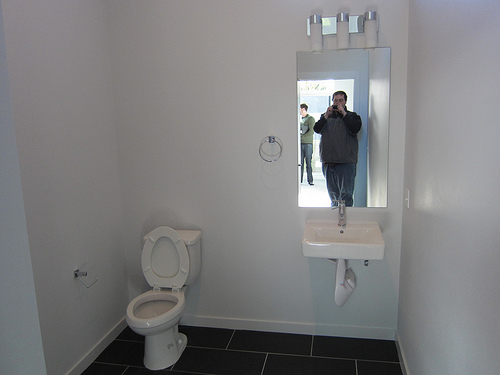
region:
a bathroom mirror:
[283, 46, 408, 195]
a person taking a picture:
[291, 43, 404, 203]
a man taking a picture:
[246, 73, 396, 190]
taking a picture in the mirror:
[303, 59, 410, 196]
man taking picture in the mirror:
[304, 74, 386, 204]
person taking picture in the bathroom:
[286, 80, 416, 205]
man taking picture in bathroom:
[293, 65, 385, 220]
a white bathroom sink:
[265, 182, 408, 316]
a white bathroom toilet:
[82, 196, 203, 373]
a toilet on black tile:
[132, 222, 332, 374]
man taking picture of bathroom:
[57, 35, 449, 331]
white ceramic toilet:
[115, 211, 215, 352]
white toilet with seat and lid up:
[122, 225, 197, 301]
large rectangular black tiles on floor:
[190, 330, 342, 365]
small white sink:
[290, 216, 386, 266]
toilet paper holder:
[66, 256, 102, 291]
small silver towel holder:
[250, 126, 281, 167]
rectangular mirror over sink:
[295, 42, 385, 238]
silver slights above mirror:
[297, 5, 373, 51]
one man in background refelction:
[301, 87, 323, 199]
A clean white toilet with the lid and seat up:
[126, 222, 191, 370]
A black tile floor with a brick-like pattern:
[78, 314, 404, 374]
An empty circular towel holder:
[255, 136, 285, 163]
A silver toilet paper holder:
[71, 260, 97, 290]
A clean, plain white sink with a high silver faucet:
[302, 205, 384, 309]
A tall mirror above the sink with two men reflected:
[295, 47, 389, 208]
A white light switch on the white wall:
[401, 188, 413, 209]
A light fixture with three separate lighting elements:
[303, 9, 382, 50]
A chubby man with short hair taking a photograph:
[313, 90, 361, 212]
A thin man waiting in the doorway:
[296, 102, 317, 185]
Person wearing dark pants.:
[313, 173, 365, 220]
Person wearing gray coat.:
[314, 135, 340, 158]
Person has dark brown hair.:
[327, 84, 354, 101]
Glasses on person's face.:
[328, 96, 403, 119]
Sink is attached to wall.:
[291, 212, 436, 344]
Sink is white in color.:
[284, 185, 409, 295]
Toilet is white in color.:
[120, 216, 205, 363]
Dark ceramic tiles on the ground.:
[193, 325, 269, 370]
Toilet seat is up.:
[118, 231, 196, 339]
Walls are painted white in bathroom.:
[125, 121, 244, 241]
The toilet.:
[121, 215, 218, 365]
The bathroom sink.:
[298, 210, 393, 311]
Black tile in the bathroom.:
[210, 332, 365, 372]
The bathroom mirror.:
[295, 40, 395, 211]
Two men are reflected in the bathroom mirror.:
[297, 93, 373, 203]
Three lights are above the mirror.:
[301, 8, 394, 48]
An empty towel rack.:
[241, 120, 291, 170]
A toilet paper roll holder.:
[60, 246, 110, 296]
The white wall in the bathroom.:
[126, 7, 286, 217]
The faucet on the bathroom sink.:
[327, 195, 361, 234]